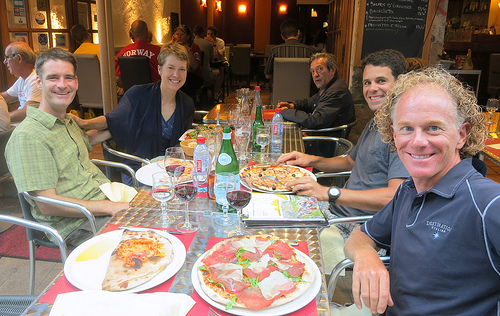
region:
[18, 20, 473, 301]
People sitting around table eating.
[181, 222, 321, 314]
A round white plate on the right.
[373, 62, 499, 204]
A man with curly hair.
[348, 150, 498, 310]
Blue short sleeve shirt.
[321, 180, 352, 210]
Writstwatch on left wrist.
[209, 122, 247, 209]
A green bottle of drink.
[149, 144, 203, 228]
Three wine glasses on the left.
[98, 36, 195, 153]
A woman with short hair.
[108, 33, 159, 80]
A red shirt.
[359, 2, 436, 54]
A chalkboard in the background.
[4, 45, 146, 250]
Man in a green plaid shirt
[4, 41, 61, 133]
Man in a white t-shirt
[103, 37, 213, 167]
Woman in a blue shirt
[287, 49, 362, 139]
Man in a black jacket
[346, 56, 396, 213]
man with brown hair and a gray shirt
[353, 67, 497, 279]
Man with curly blonde hair and a gray shirt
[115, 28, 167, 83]
Person wearing a red shirt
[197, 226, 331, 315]
Plate with food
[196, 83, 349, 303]
Plate with food and drinks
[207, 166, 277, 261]
Wine glass with red wine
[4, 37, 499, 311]
five people sitting at a table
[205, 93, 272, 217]
two green bottles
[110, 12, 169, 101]
the shirt is red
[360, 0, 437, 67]
a chalkboard with white writing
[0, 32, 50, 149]
the man is balding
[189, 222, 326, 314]
a pizza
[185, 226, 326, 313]
a red placemat is under the white plate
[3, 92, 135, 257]
the shirt is green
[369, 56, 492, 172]
the man's hair is blond and curly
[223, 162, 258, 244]
the wineglass is half full of red wine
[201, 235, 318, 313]
Steak carpaccio is on a plate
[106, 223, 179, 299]
An oddly shaped taco is on a plate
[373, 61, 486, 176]
A balding man's hair is curly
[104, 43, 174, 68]
Red shirt that says norway on it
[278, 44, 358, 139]
Man seems fed up with situation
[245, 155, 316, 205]
Pizza is sliced up on a dish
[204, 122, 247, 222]
Spritzer bottle is open and empty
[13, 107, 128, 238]
Man's shirt is green and striped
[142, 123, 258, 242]
Wine glasses are nearly empty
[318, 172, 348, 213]
Man's watch rests on his arm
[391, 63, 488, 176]
Man with curly hair looking at camera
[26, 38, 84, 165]
Man in green shirt smiling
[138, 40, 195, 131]
Woman in blue shirt smiling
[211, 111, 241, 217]
Green bottle on table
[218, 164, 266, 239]
Glass with red wine on table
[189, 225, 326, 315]
Pizza on white plate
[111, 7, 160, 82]
Man in red shirt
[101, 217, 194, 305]
White plate on red placemat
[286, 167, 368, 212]
Man wearing watch and ring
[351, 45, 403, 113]
Man with brown hair smiling